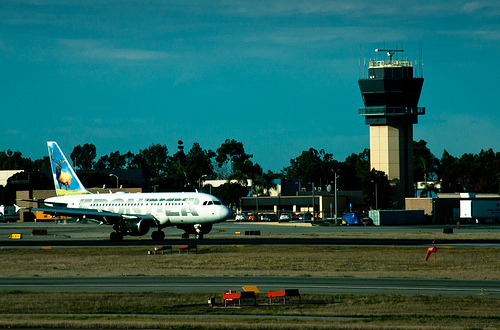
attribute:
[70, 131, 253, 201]
tree line — green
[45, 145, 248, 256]
jetliner — large